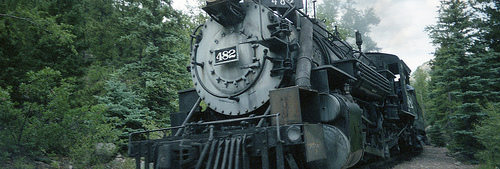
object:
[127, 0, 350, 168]
train front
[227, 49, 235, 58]
number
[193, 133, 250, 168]
grate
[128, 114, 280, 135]
rail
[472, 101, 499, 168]
trees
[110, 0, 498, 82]
sky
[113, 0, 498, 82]
clouds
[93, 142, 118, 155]
rock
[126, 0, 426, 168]
train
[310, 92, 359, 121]
engine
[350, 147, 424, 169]
train track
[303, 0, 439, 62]
smoke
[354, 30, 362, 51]
whistle